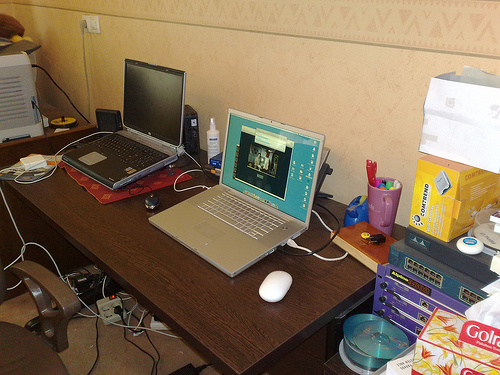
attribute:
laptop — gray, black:
[55, 51, 194, 194]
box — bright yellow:
[406, 163, 498, 237]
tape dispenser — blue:
[342, 194, 359, 222]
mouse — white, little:
[256, 270, 293, 302]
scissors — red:
[362, 155, 382, 184]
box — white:
[414, 65, 498, 175]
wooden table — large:
[7, 139, 375, 373]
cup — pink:
[368, 177, 403, 241]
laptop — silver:
[146, 107, 325, 277]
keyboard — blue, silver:
[198, 189, 290, 242]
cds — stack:
[335, 312, 413, 369]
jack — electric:
[271, 211, 393, 283]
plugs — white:
[98, 293, 158, 334]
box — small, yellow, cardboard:
[409, 158, 497, 242]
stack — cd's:
[342, 307, 409, 366]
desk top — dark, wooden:
[105, 268, 263, 367]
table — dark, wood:
[9, 126, 410, 361]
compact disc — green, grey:
[335, 316, 405, 369]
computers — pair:
[63, 52, 383, 304]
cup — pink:
[364, 177, 435, 241]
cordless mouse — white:
[253, 263, 338, 343]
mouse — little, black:
[142, 195, 158, 214]